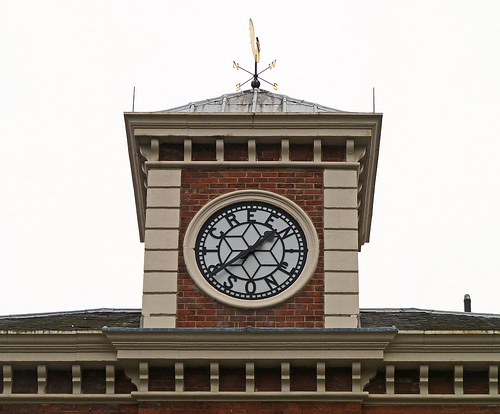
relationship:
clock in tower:
[181, 176, 326, 319] [128, 98, 379, 329]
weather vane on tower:
[233, 23, 293, 93] [128, 98, 379, 329]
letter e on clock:
[245, 203, 257, 223] [181, 176, 326, 319]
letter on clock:
[256, 275, 288, 291] [181, 176, 326, 319]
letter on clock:
[203, 242, 226, 262] [181, 176, 326, 319]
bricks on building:
[303, 178, 323, 205] [7, 316, 163, 402]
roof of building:
[369, 310, 498, 332] [7, 316, 163, 402]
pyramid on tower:
[196, 84, 325, 122] [128, 98, 379, 329]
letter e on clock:
[248, 198, 261, 223] [181, 176, 326, 319]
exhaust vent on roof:
[460, 286, 481, 318] [369, 310, 498, 332]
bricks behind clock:
[303, 178, 323, 205] [181, 176, 326, 319]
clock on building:
[181, 176, 326, 319] [7, 316, 163, 402]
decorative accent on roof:
[401, 329, 499, 361] [369, 310, 498, 332]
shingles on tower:
[324, 164, 359, 330] [128, 98, 379, 329]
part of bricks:
[314, 182, 324, 188] [303, 178, 323, 205]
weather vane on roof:
[233, 23, 293, 93] [369, 310, 498, 332]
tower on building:
[128, 98, 379, 329] [7, 316, 163, 402]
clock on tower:
[181, 176, 326, 319] [128, 98, 379, 329]